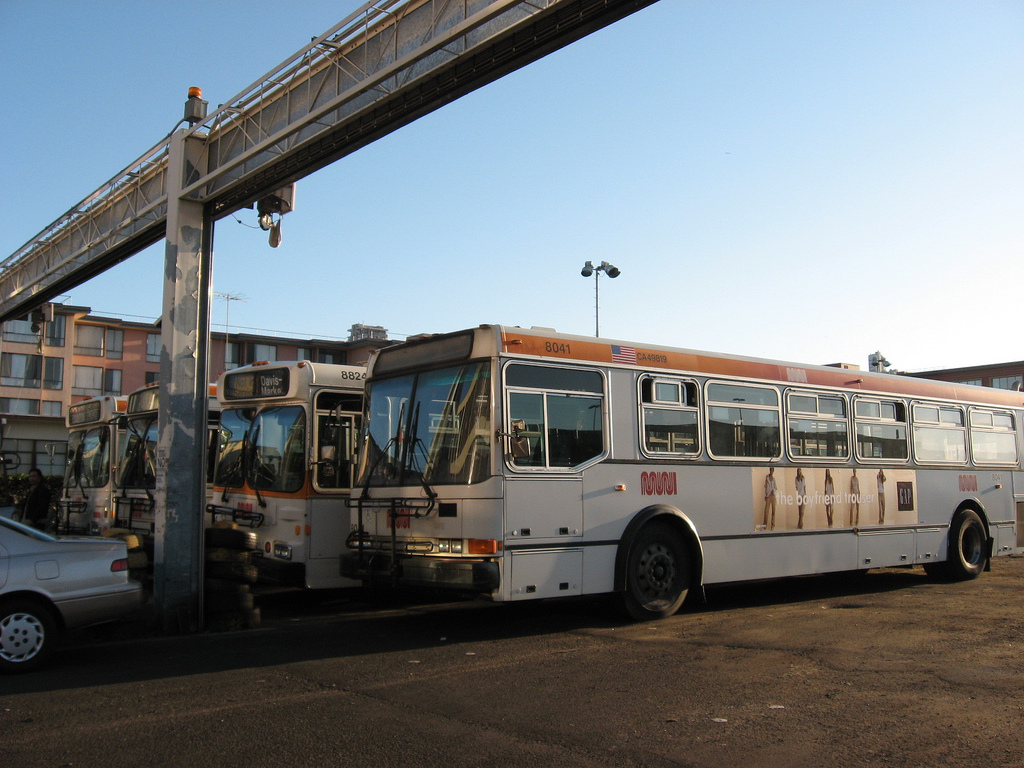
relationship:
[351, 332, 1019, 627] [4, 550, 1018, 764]
bus on road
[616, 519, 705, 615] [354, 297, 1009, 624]
wheel on bus